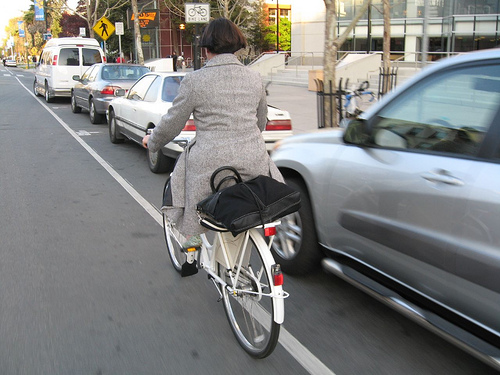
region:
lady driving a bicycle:
[142, 28, 269, 374]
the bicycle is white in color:
[203, 242, 288, 340]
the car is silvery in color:
[338, 148, 481, 302]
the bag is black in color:
[217, 187, 318, 216]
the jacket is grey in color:
[188, 77, 260, 159]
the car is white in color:
[46, 48, 66, 90]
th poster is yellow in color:
[81, 13, 127, 34]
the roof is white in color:
[297, 23, 326, 52]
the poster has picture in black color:
[99, 23, 117, 38]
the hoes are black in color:
[178, 265, 203, 276]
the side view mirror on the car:
[338, 116, 368, 145]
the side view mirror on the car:
[113, 88, 125, 97]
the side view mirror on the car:
[71, 73, 81, 81]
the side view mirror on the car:
[30, 55, 37, 63]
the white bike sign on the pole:
[183, 3, 210, 24]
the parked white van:
[32, 36, 106, 103]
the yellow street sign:
[90, 14, 115, 39]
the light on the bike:
[262, 226, 276, 236]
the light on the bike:
[272, 273, 282, 286]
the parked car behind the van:
[71, 62, 151, 125]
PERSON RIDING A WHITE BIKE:
[141, 10, 322, 347]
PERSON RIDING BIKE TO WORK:
[128, 14, 326, 354]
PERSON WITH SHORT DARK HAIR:
[131, 8, 313, 295]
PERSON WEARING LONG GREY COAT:
[103, 15, 328, 287]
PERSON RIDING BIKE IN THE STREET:
[15, 6, 345, 368]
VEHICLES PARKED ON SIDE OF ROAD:
[27, 18, 498, 353]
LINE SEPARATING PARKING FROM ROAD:
[9, 69, 307, 374]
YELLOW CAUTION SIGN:
[83, 6, 131, 53]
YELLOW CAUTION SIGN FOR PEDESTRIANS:
[88, 7, 165, 85]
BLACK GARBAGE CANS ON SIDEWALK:
[308, 50, 408, 132]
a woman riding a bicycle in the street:
[136, 23, 316, 364]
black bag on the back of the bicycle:
[186, 154, 308, 255]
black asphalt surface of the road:
[37, 258, 137, 351]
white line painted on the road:
[83, 152, 140, 203]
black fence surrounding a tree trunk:
[311, 77, 348, 126]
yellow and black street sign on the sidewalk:
[91, 18, 115, 49]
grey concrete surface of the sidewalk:
[279, 86, 307, 111]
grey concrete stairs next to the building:
[275, 55, 305, 87]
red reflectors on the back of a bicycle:
[258, 214, 290, 298]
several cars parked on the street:
[34, 30, 201, 174]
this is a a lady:
[154, 29, 288, 196]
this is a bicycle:
[209, 240, 316, 357]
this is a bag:
[218, 184, 287, 234]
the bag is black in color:
[227, 187, 272, 234]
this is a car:
[122, 66, 157, 118]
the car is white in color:
[128, 101, 145, 113]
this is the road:
[25, 107, 89, 228]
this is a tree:
[101, 16, 133, 46]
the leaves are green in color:
[110, 10, 127, 17]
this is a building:
[396, 17, 463, 60]